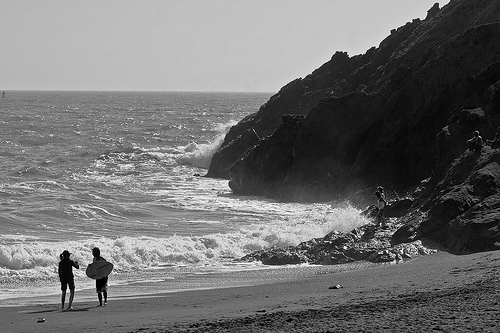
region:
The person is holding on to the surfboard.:
[79, 243, 118, 308]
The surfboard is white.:
[86, 260, 123, 280]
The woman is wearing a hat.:
[61, 248, 74, 258]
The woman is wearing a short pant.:
[53, 278, 80, 290]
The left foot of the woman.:
[59, 304, 66, 311]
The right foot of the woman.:
[66, 290, 80, 312]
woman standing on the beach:
[56, 249, 80, 311]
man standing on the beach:
[86, 247, 115, 307]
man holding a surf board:
[84, 260, 114, 279]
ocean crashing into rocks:
[207, 20, 499, 266]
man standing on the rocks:
[371, 182, 387, 231]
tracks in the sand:
[105, 251, 497, 331]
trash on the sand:
[327, 282, 344, 289]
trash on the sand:
[35, 315, 45, 325]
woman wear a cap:
[60, 250, 70, 257]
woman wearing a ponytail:
[57, 252, 64, 260]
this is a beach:
[0, 168, 470, 329]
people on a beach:
[41, 225, 137, 305]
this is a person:
[45, 238, 87, 315]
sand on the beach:
[157, 255, 384, 308]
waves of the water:
[23, 206, 298, 284]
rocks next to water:
[185, 12, 480, 246]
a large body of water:
[5, 50, 282, 290]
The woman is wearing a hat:
[58, 243, 70, 255]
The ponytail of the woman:
[56, 250, 63, 260]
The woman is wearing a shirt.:
[54, 261, 76, 271]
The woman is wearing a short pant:
[59, 278, 81, 291]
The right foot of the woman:
[65, 277, 81, 305]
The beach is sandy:
[8, 253, 497, 331]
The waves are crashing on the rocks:
[173, 113, 225, 172]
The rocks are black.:
[213, 48, 493, 263]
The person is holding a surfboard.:
[84, 239, 127, 303]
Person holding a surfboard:
[85, 248, 111, 308]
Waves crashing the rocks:
[209, 187, 385, 264]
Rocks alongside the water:
[207, 0, 496, 267]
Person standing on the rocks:
[372, 185, 392, 230]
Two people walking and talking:
[55, 245, 116, 312]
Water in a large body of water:
[0, 85, 387, 269]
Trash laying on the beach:
[325, 282, 346, 291]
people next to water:
[35, 225, 141, 310]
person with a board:
[76, 235, 127, 304]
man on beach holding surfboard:
[83, 242, 116, 307]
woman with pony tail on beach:
[52, 246, 82, 316]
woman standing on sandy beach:
[53, 245, 85, 313]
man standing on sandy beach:
[84, 242, 115, 310]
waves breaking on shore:
[0, 193, 380, 294]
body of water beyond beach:
[0, 77, 385, 308]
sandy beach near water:
[3, 254, 497, 331]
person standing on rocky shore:
[367, 180, 391, 235]